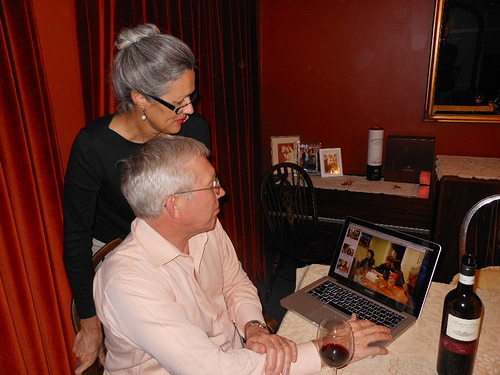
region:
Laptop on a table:
[273, 211, 443, 346]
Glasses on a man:
[179, 174, 219, 195]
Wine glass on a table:
[315, 315, 353, 374]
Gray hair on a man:
[112, 135, 204, 215]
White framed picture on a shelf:
[315, 147, 344, 175]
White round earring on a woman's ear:
[140, 106, 145, 122]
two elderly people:
[58, 18, 397, 373]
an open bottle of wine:
[435, 249, 484, 373]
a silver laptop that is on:
[276, 215, 441, 362]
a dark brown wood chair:
[258, 162, 343, 308]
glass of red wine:
[313, 312, 359, 372]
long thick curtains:
[0, 0, 268, 373]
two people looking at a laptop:
[61, 15, 451, 373]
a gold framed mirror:
[422, 2, 498, 127]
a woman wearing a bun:
[106, 12, 198, 138]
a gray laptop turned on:
[259, 210, 445, 354]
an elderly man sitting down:
[47, 136, 397, 367]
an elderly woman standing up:
[25, 17, 260, 369]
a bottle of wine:
[434, 233, 485, 374]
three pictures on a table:
[264, 128, 346, 180]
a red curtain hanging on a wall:
[3, 3, 289, 338]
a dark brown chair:
[238, 157, 359, 317]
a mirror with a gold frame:
[421, 4, 498, 130]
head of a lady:
[96, 29, 233, 139]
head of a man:
[121, 131, 247, 256]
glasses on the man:
[187, 163, 239, 210]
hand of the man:
[233, 311, 308, 372]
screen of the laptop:
[306, 223, 433, 300]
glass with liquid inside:
[297, 311, 367, 373]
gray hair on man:
[116, 125, 211, 210]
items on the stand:
[253, 113, 434, 197]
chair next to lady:
[237, 156, 348, 283]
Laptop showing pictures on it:
[281, 196, 448, 373]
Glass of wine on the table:
[313, 311, 360, 373]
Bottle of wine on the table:
[436, 239, 491, 374]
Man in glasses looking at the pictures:
[99, 126, 348, 373]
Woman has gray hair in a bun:
[108, 16, 203, 140]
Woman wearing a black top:
[48, 103, 251, 353]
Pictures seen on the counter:
[274, 111, 446, 199]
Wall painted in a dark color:
[267, 9, 431, 169]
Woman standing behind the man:
[32, 23, 242, 370]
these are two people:
[37, 37, 408, 368]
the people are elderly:
[94, 57, 289, 349]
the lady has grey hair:
[114, 38, 226, 130]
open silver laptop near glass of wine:
[277, 213, 441, 374]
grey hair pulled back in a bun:
[110, 19, 197, 111]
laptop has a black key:
[327, 279, 332, 285]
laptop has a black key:
[325, 284, 330, 290]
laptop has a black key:
[342, 288, 349, 293]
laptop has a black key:
[348, 290, 354, 296]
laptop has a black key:
[353, 292, 358, 299]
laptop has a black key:
[359, 298, 365, 303]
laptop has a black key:
[364, 300, 370, 306]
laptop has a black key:
[376, 305, 381, 310]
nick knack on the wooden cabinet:
[268, 132, 298, 168]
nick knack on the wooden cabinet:
[316, 145, 342, 176]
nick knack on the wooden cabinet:
[366, 125, 383, 175]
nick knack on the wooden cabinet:
[380, 130, 433, 183]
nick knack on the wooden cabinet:
[418, 167, 431, 187]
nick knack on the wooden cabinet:
[390, 182, 400, 189]